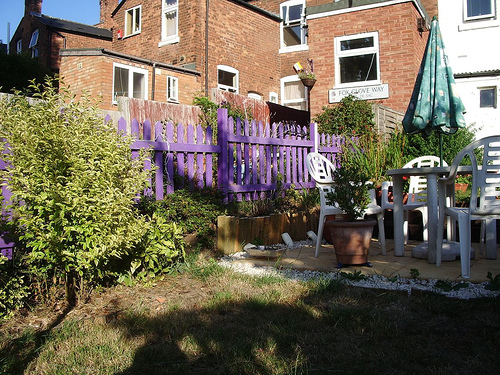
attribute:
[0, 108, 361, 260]
picket fence — purple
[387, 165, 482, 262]
table — white, round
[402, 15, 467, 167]
umbrella — blue, closed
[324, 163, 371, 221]
plant — growing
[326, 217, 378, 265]
pot — red, brown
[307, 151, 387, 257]
chair — white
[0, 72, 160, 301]
bush — small, green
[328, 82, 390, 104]
sign — white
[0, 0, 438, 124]
building — large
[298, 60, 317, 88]
basket — hanging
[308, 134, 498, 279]
furniture — white